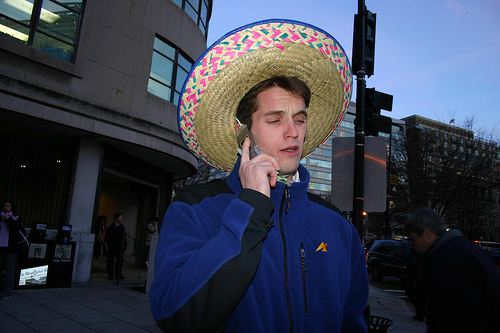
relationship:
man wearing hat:
[147, 18, 372, 330] [175, 19, 354, 174]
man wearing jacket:
[147, 18, 372, 330] [147, 159, 380, 331]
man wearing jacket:
[147, 18, 372, 330] [147, 185, 359, 326]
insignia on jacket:
[308, 234, 332, 256] [147, 159, 380, 331]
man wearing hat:
[147, 18, 372, 330] [178, 12, 351, 169]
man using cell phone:
[147, 18, 372, 330] [232, 128, 262, 171]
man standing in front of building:
[147, 18, 372, 330] [2, 0, 215, 280]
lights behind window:
[0, 0, 62, 47] [1, 0, 92, 80]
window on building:
[1, 0, 92, 80] [2, 0, 215, 280]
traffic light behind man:
[353, 0, 383, 255] [147, 18, 372, 330]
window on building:
[144, 34, 199, 108] [2, 0, 215, 280]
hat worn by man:
[178, 12, 351, 169] [147, 18, 372, 330]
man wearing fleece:
[147, 18, 372, 330] [148, 151, 374, 331]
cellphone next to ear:
[233, 122, 262, 159] [231, 120, 242, 132]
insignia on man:
[308, 234, 332, 256] [147, 18, 372, 330]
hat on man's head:
[178, 12, 351, 169] [236, 79, 313, 175]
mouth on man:
[276, 133, 313, 160] [163, 62, 382, 228]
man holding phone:
[147, 18, 372, 330] [232, 117, 253, 159]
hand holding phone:
[234, 130, 284, 199] [232, 117, 253, 159]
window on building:
[144, 34, 199, 108] [87, 6, 210, 148]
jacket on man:
[109, 204, 160, 256] [185, 84, 343, 276]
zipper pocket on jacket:
[260, 227, 345, 324] [147, 159, 380, 331]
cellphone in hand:
[233, 122, 262, 159] [236, 134, 281, 209]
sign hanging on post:
[328, 135, 389, 213] [353, 0, 364, 237]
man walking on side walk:
[147, 18, 372, 330] [0, 261, 181, 329]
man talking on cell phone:
[147, 18, 372, 330] [234, 123, 261, 160]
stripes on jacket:
[151, 164, 360, 327] [147, 159, 380, 331]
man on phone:
[147, 18, 372, 330] [233, 125, 255, 160]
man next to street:
[147, 18, 372, 330] [366, 242, 499, 302]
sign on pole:
[355, 74, 366, 225] [341, 6, 386, 216]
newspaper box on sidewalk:
[43, 217, 80, 287] [0, 270, 157, 325]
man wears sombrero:
[147, 18, 372, 330] [130, 40, 426, 145]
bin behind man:
[367, 312, 394, 331] [147, 18, 372, 330]